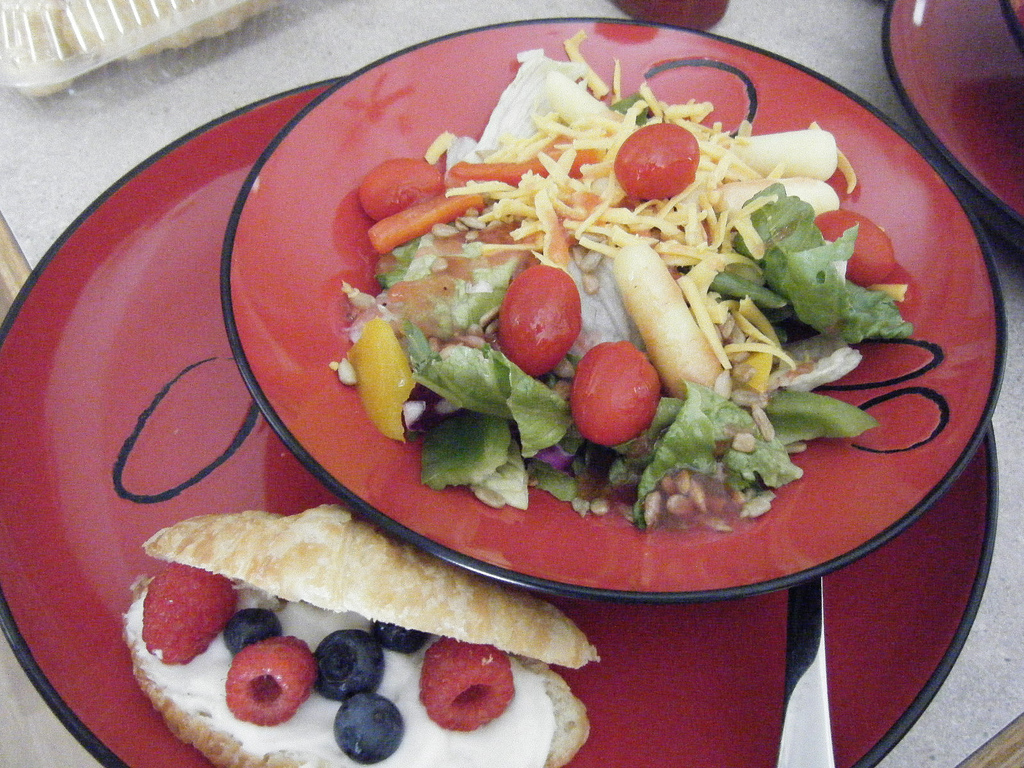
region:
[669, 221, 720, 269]
cheese in the salad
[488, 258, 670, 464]
two tomatoes on the salad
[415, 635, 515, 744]
raspberry on the tart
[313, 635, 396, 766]
blueberries on the tart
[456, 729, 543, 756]
cream on the tart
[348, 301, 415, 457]
yellow pepper on the plate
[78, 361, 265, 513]
black design on the red plate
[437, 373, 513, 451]
lettuce on the plate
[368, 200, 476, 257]
carrot slice on the salad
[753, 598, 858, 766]
untensil on the plate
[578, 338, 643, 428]
Red olive on top of the salad.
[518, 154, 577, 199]
Shredded cheese on top of the salad.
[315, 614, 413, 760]
Purple olives on top of the cream.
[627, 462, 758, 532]
Salad dressing on the salad.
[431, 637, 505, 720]
Red raspberries on the cream.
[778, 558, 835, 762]
Silver utensil on top of the plate.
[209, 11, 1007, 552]
Bowl sitting on top of the plate.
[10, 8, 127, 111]
Container sitting on top of the counter.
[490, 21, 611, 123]
Piece of lettuce in the bowl.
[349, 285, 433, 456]
Cut up food on the side of the salad.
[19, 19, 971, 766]
two plates of food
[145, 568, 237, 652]
a raspberry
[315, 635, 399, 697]
a blueberry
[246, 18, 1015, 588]
food on a plate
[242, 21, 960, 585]
a salad on a red plate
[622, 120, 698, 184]
a cherry tomato on the salad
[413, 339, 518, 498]
lettuce on the plate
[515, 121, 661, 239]
cheese on the salad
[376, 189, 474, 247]
a carrot on the plate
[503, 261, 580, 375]
tomato on the plate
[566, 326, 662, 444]
tomato in the salad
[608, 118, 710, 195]
red tomato on plate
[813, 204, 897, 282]
red tomato on plate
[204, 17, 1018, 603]
red and black plate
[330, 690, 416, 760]
blueberry on the bread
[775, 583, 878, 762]
handle on silver utensil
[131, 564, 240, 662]
raspberry on the bread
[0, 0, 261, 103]
container on the table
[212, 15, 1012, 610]
Plate of vegetable salad with cheese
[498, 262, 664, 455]
Two cherry tomatoes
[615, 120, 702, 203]
one cherry tomato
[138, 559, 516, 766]
Raspberries and blueberries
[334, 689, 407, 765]
One small blueberry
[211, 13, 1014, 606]
Vegetable salad on salad plate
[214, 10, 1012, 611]
Red salad plate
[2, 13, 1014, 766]
Salad plate on a plate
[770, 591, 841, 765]
Handle grip of silver utensil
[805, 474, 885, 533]
the plate is red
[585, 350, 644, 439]
a red tomatoe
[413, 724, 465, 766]
whip cream on the crossiant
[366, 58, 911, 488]
food on the plate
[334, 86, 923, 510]
Food on the plate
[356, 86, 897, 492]
Food on red plate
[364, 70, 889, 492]
Food on red plate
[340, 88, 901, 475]
Salad on the plate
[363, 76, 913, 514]
Salad on red plate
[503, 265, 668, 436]
Tomatoes on the plate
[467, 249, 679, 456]
Tomatoes on red plate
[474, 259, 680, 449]
Tomatoes on the salad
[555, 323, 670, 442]
Tomato on the salad